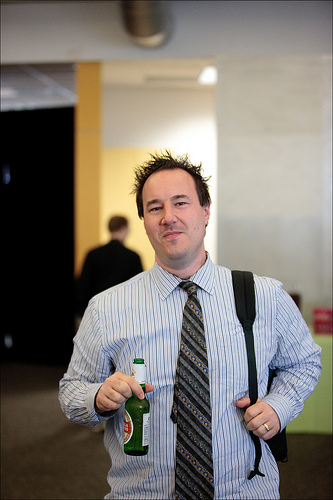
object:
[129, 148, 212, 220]
hair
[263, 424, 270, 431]
wedding band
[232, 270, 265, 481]
strap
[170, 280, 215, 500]
tie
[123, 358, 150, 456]
bottle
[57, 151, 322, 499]
man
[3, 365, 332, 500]
carpet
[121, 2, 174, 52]
tube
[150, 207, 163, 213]
eye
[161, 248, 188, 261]
stubble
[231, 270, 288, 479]
back pack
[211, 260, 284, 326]
left shoulder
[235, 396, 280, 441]
hand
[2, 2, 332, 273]
wall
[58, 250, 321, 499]
shirt